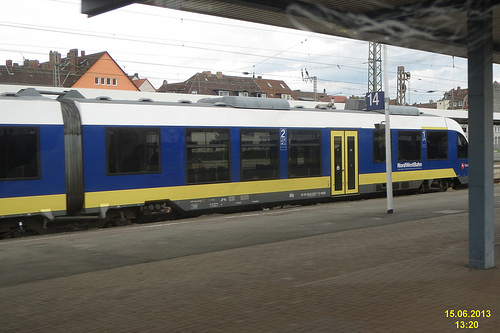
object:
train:
[5, 82, 498, 217]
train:
[0, 96, 470, 238]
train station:
[1, 0, 499, 331]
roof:
[3, 50, 138, 86]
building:
[156, 71, 295, 100]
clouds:
[0, 0, 434, 73]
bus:
[6, 72, 468, 218]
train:
[28, 43, 482, 261]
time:
[454, 319, 481, 329]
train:
[170, 100, 332, 203]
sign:
[363, 89, 391, 116]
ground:
[0, 181, 500, 281]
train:
[117, 85, 374, 200]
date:
[454, 320, 479, 330]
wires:
[150, 24, 227, 87]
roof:
[164, 64, 265, 95]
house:
[4, 46, 154, 94]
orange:
[90, 52, 122, 74]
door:
[331, 130, 345, 196]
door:
[345, 131, 359, 194]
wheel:
[135, 202, 168, 212]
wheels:
[0, 175, 463, 235]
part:
[439, 180, 444, 186]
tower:
[391, 68, 445, 123]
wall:
[167, 90, 247, 140]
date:
[444, 309, 492, 319]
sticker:
[455, 161, 470, 173]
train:
[166, 85, 472, 202]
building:
[0, 49, 143, 93]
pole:
[454, 9, 499, 276]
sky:
[146, 18, 254, 69]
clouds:
[386, 54, 499, 105]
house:
[159, 77, 263, 103]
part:
[139, 204, 166, 214]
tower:
[366, 37, 385, 100]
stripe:
[0, 159, 458, 219]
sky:
[4, 5, 495, 105]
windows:
[100, 126, 320, 191]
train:
[0, 77, 480, 248]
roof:
[5, 48, 107, 86]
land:
[0, 141, 497, 331]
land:
[6, 94, 497, 328]